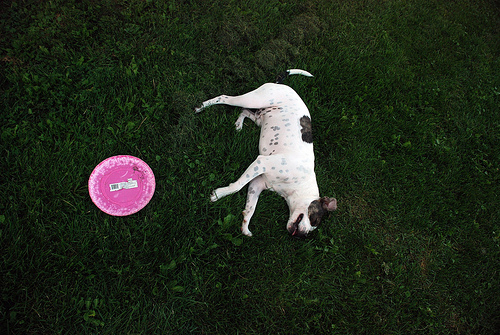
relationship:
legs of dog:
[207, 158, 264, 235] [200, 68, 341, 248]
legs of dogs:
[189, 86, 265, 133] [187, 59, 347, 246]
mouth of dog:
[288, 211, 309, 232] [180, 57, 339, 256]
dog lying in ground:
[224, 62, 337, 242] [13, 10, 178, 126]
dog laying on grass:
[192, 69, 337, 237] [58, 28, 180, 137]